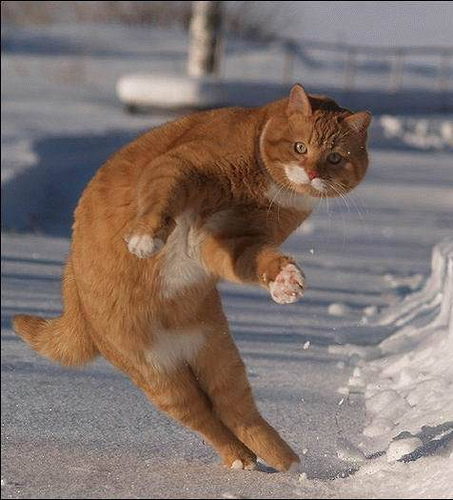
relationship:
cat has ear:
[14, 78, 375, 476] [285, 85, 321, 120]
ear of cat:
[285, 85, 321, 120] [14, 78, 375, 476]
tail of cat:
[8, 286, 113, 374] [14, 78, 375, 476]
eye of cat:
[284, 136, 309, 164] [14, 78, 375, 476]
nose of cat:
[309, 148, 341, 191] [14, 78, 375, 476]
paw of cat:
[127, 206, 182, 279] [14, 78, 375, 476]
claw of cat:
[272, 269, 305, 306] [14, 78, 375, 476]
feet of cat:
[254, 422, 300, 474] [14, 78, 375, 476]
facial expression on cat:
[278, 107, 363, 210] [14, 78, 375, 476]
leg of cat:
[205, 340, 301, 464] [14, 78, 375, 476]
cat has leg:
[14, 78, 375, 476] [205, 340, 301, 464]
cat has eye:
[14, 78, 375, 476] [284, 136, 309, 164]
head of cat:
[227, 79, 394, 206] [14, 78, 375, 476]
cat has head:
[14, 78, 375, 476] [227, 79, 394, 206]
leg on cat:
[205, 340, 301, 464] [14, 78, 375, 476]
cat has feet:
[14, 78, 375, 476] [184, 397, 384, 493]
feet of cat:
[184, 397, 384, 493] [14, 78, 375, 476]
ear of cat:
[341, 109, 374, 134] [14, 78, 375, 476]